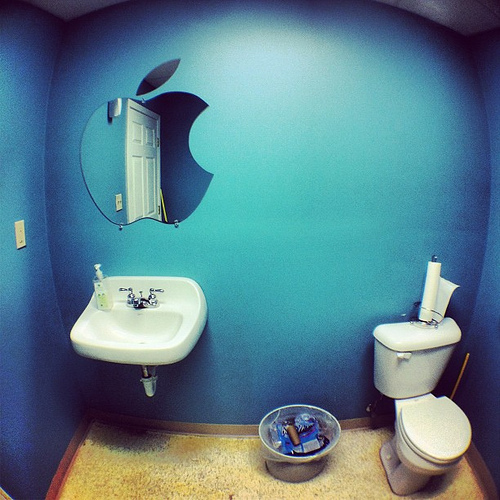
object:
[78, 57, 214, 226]
mirror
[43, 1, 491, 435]
wall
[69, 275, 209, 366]
sink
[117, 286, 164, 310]
faucet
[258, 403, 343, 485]
garbage can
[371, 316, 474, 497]
toilet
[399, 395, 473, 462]
lid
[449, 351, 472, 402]
plunger handle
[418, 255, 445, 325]
paper towel holder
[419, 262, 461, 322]
roll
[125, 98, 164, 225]
door reflection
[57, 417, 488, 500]
floor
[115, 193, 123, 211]
light switch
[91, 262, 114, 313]
hand soap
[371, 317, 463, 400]
tank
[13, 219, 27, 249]
switch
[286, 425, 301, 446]
toilet paper roll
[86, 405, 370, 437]
floor board